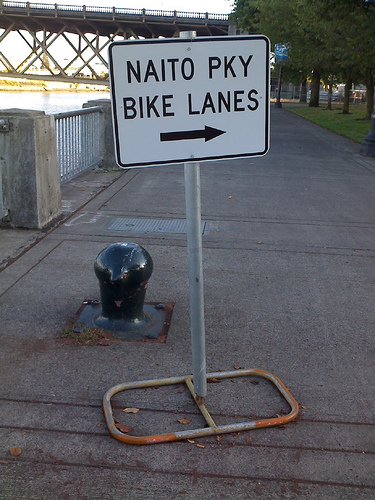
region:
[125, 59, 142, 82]
black letter on white sign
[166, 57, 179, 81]
blue colored paper napkin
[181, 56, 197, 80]
blue colored paper napkin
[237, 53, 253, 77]
blue colored paper napkin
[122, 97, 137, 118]
blue colored paper napkin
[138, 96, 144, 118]
blue colored paper napkin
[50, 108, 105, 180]
a silver fence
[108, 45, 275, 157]
a sign with an arrow on it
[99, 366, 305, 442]
the base of the sign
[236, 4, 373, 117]
trees on the side of the picture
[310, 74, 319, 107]
the trunk of the tree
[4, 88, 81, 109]
water under the bridge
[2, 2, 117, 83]
a bridge above the water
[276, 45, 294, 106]
a sign along the sidewalk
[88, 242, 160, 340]
a black stub in the sidewalk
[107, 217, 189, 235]
a silver storm drain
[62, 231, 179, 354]
round black pole in the ground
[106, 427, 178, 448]
metal stand bottom is rusted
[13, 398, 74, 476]
grooves in the pavement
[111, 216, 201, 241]
metal cover over hole in the pavement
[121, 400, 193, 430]
leaves on the sidewalk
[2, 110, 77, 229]
cement post on the edge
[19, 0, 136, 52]
bridge going over the water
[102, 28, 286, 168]
sign on a pole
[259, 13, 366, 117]
trees off to the side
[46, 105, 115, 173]
guardrail by the water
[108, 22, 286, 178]
street sign pointing to bike lanes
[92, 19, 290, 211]
sign pointing to bike lanes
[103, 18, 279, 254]
metal stand pointing to bike lanes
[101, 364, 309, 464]
rusted stand of sign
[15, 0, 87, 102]
large bridge over river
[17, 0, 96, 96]
tall bridge over water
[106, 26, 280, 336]
bike lanes at park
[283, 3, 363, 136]
grass and trees at park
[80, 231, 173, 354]
short black bench at park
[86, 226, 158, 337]
small black bench at park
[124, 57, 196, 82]
The word Naito on the sign.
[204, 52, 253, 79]
The letters PKY on the sign.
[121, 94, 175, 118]
The word Bike on the sign.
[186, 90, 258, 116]
The word Lanes on the sign.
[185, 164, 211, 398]
The pole the sign is mounted on.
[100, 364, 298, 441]
The stand of the sign.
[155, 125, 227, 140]
The black arrow on the sign.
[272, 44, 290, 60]
The blue sign in the background.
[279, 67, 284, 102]
The pole the blue sign is mounted on.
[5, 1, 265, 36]
The bridge in the background.